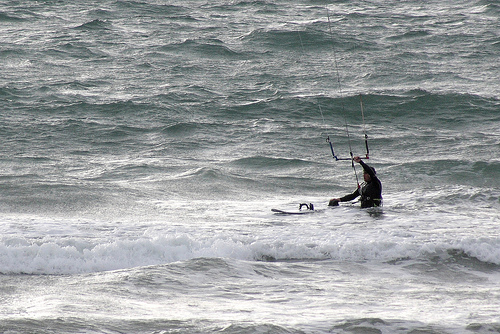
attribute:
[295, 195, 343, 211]
handle — kite  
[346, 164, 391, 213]
wetsuit — black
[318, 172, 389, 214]
suit — black wet 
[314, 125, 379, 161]
kite handle — black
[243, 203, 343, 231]
surfboard — water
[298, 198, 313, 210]
foot strap — empty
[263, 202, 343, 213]
board — raised